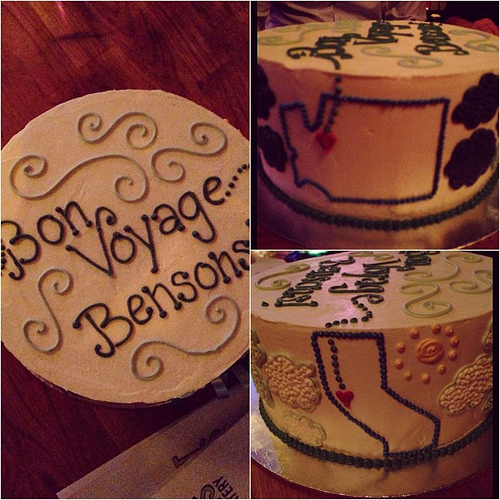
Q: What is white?
A: Frosting.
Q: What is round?
A: Cake.